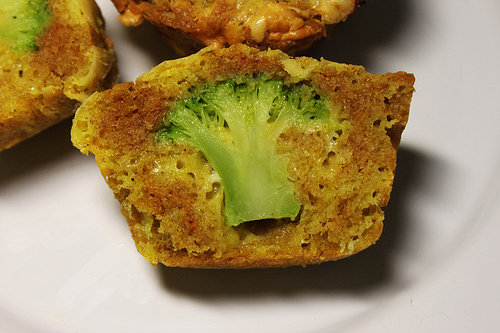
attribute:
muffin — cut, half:
[81, 65, 401, 269]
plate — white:
[13, 189, 160, 327]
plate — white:
[22, 208, 172, 311]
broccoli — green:
[185, 99, 335, 227]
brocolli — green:
[143, 82, 364, 241]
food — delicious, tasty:
[64, 16, 446, 330]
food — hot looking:
[88, 28, 484, 295]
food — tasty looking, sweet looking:
[76, 41, 464, 313]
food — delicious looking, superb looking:
[87, 45, 470, 292]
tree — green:
[157, 54, 378, 241]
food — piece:
[80, 26, 452, 298]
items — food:
[98, 25, 445, 290]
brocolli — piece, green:
[154, 62, 366, 250]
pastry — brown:
[100, 39, 440, 320]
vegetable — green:
[146, 59, 384, 255]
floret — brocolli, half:
[160, 75, 340, 249]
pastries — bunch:
[39, 7, 475, 299]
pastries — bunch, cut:
[92, 38, 484, 275]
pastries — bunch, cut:
[71, 31, 421, 320]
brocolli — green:
[151, 62, 356, 241]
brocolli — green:
[149, 67, 396, 261]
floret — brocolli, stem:
[155, 63, 384, 238]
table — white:
[28, 159, 278, 330]